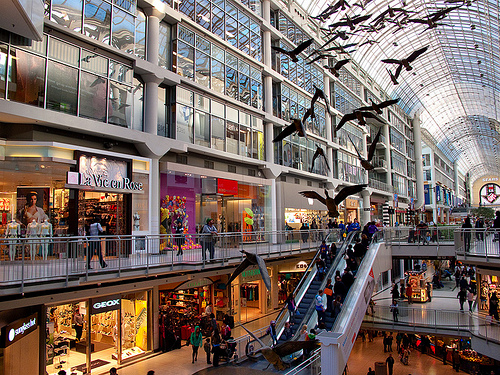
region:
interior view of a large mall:
[3, 1, 495, 371]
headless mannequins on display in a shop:
[2, 183, 72, 265]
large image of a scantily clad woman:
[14, 184, 51, 227]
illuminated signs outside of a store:
[2, 291, 149, 373]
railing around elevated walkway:
[367, 271, 499, 373]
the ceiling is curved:
[305, 1, 499, 183]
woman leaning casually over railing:
[193, 214, 232, 264]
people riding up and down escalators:
[249, 215, 381, 351]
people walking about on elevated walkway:
[371, 256, 498, 347]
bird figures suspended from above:
[226, 1, 472, 293]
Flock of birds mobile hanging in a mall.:
[274, 0, 477, 218]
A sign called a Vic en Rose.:
[72, 148, 149, 290]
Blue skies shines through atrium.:
[183, 3, 260, 81]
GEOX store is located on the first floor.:
[84, 298, 126, 360]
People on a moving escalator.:
[314, 202, 382, 345]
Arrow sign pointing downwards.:
[482, 178, 498, 205]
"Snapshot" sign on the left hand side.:
[9, 314, 48, 341]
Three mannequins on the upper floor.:
[7, 216, 54, 265]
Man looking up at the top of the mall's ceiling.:
[197, 214, 222, 259]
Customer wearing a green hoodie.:
[189, 323, 203, 348]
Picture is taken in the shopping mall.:
[27, 15, 483, 346]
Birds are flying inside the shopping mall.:
[217, 10, 448, 332]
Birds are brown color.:
[205, 210, 345, 361]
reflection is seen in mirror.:
[45, 20, 351, 106]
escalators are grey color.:
[277, 233, 359, 353]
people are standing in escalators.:
[280, 225, 362, 345]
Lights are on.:
[8, 160, 333, 355]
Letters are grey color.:
[68, 165, 143, 193]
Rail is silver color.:
[12, 226, 289, 294]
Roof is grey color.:
[381, 15, 498, 142]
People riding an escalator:
[280, 213, 380, 368]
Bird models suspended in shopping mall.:
[270, 0, 463, 222]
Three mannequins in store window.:
[5, 213, 52, 263]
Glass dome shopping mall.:
[395, 27, 499, 239]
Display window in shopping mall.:
[121, 298, 148, 360]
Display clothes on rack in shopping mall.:
[239, 277, 258, 312]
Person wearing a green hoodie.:
[185, 323, 204, 353]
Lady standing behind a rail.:
[196, 216, 221, 264]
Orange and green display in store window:
[238, 208, 256, 243]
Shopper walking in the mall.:
[431, 257, 489, 322]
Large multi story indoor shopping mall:
[0, 0, 492, 370]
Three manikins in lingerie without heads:
[3, 215, 53, 257]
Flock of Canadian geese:
[226, 0, 471, 371]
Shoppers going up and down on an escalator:
[237, 230, 388, 371]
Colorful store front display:
[160, 192, 196, 244]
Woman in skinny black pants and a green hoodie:
[188, 325, 203, 365]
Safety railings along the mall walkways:
[360, 302, 496, 340]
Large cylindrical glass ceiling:
[1, 0, 496, 206]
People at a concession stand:
[388, 270, 433, 303]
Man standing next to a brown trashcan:
[373, 351, 396, 373]